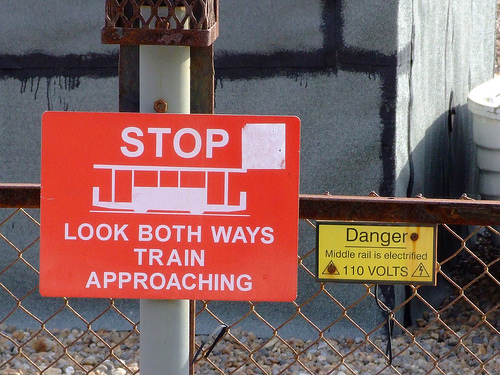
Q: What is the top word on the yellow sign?
A: Danger.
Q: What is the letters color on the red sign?
A: White.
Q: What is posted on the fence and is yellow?
A: Sign.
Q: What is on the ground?
A: Rocks.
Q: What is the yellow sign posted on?
A: Fence.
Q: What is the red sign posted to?
A: Pole.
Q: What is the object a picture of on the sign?
A: Train.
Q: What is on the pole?
A: Sign.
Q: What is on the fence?
A: Danger sign.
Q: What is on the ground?
A: Pebbles.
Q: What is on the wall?
A: Black paint.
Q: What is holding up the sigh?
A: White pole.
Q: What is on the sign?
A: White writing.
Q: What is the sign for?
A: Electric warning.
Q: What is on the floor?
A: Pole.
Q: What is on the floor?
A: Fence.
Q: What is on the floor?
A: Pole.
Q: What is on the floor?
A: Danger sign.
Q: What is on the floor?
A: Painting.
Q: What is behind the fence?
A: Stones.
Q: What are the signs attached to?
A: A fence.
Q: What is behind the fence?
A: A wall.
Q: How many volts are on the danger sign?
A: 110 volts.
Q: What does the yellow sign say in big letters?
A: Danger 110 Volts.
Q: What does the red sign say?
A: Stop look both ways train approaching.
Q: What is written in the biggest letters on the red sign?
A: Stop.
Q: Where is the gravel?
A: On the ground.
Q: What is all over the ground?
A: Gravel.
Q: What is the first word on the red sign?
A: STOP.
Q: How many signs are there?
A: Two.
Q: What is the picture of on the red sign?
A: Train.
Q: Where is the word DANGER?
A: Yellow sign.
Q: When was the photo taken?
A: Daytime.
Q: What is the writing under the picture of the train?
A: Look both ways train approaching.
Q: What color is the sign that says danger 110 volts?
A: Yellow.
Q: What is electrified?
A: Middle rail.